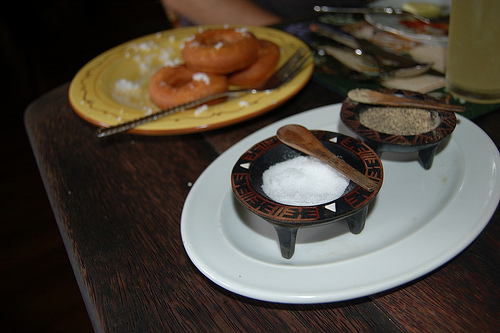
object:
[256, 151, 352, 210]
salt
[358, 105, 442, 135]
pepper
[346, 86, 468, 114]
spoon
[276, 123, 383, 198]
spoon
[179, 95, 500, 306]
dish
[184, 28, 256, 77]
donut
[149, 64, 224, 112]
donut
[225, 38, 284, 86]
donut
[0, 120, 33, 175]
ground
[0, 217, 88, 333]
ground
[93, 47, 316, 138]
fork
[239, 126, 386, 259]
bowl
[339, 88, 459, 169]
bowl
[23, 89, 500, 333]
table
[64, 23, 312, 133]
plate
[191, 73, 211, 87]
sugar